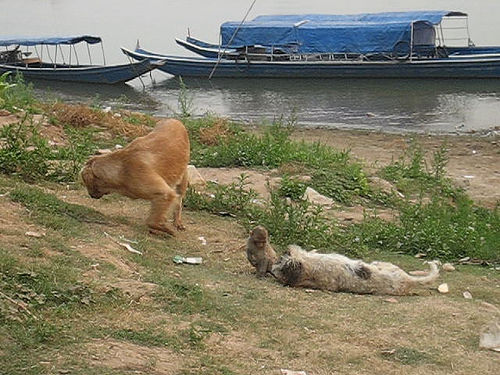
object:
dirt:
[479, 149, 499, 181]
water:
[211, 78, 500, 137]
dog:
[238, 224, 436, 295]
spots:
[282, 259, 303, 287]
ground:
[0, 252, 146, 326]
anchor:
[134, 40, 141, 54]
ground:
[173, 304, 392, 364]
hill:
[0, 138, 499, 374]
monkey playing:
[242, 222, 448, 297]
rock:
[363, 176, 398, 195]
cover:
[219, 18, 421, 57]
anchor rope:
[208, 1, 258, 80]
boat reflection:
[166, 75, 498, 103]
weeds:
[248, 204, 259, 224]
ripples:
[232, 112, 248, 115]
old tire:
[393, 41, 411, 61]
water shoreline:
[164, 111, 496, 139]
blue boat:
[0, 35, 153, 82]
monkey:
[244, 223, 439, 296]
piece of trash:
[174, 256, 203, 265]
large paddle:
[125, 55, 145, 87]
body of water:
[86, 88, 116, 96]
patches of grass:
[277, 150, 295, 162]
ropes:
[218, 39, 221, 52]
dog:
[74, 118, 192, 238]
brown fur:
[128, 155, 149, 169]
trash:
[25, 230, 41, 237]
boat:
[122, 21, 499, 78]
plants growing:
[6, 71, 66, 192]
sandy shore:
[185, 109, 499, 150]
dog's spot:
[356, 263, 372, 279]